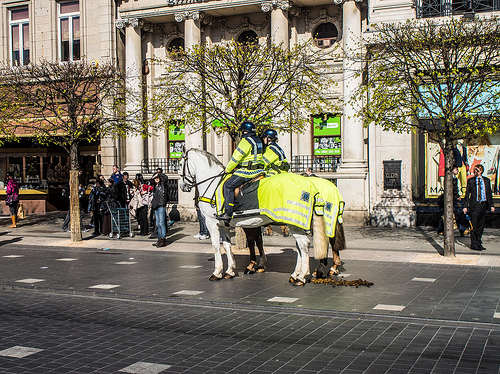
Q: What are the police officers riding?
A: Horses.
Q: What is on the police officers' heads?
A: Helmets.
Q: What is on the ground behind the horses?
A: Feces.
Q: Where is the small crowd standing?
A: Sidewalk.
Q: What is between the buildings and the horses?
A: Trees.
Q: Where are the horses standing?
A: Street.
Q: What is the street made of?
A: Stone bricks.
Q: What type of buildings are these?
A: Stores.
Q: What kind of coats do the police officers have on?
A: Safety/ Reflection Coats.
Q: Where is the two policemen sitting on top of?
A: Horse.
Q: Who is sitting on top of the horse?
A: A man.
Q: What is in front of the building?
A: Tree.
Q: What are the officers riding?
A: Horses.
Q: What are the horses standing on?
A: Road.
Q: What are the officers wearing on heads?
A: Helmets.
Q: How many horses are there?
A: 2.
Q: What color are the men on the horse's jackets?
A: Yellow and black.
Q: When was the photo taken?
A: Daytime.